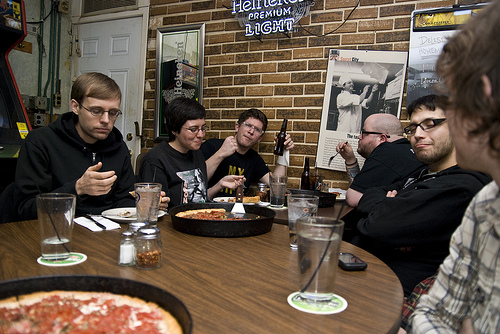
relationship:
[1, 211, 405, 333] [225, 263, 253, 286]
table made of wood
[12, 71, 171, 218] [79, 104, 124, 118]
man has on eyeglasses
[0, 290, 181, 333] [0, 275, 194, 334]
pizza in a pan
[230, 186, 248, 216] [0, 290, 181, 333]
spatula in pizza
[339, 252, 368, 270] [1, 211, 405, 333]
cellphone on table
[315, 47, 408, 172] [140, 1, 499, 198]
poster on wall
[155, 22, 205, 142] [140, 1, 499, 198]
mirror on wall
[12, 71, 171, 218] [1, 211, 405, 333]
man at a table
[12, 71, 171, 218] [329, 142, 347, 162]
man has a fork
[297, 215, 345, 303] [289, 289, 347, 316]
glass on a coaster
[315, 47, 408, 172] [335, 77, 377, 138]
poster has a man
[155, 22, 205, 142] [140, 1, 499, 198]
mirror on a wall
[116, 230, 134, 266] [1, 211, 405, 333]
salt shaker on a table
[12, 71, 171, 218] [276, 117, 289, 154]
man has a beer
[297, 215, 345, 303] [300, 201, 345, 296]
glass has a straw